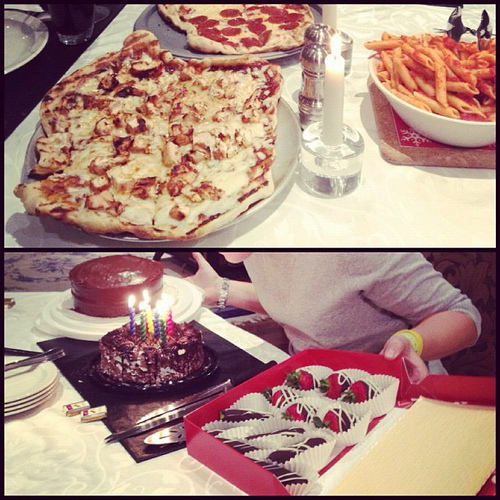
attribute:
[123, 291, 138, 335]
candle — lit, birthday candle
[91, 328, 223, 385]
cake — brown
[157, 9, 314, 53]
pepperoni pizza — cooked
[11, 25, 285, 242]
pizza — freshly cooked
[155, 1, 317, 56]
pizza — freshly cooked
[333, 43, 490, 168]
bowl — white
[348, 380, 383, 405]
strawberries — chocolate covered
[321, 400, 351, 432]
strawberries — chocolate covered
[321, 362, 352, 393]
strawberries — chocolate covered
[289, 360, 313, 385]
strawberries — chocolate covered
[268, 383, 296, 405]
strawberries — chocolate covered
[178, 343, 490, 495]
container — red, plastic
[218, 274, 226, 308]
accessory — worn, wrist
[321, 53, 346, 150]
candle — white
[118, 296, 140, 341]
candle — purple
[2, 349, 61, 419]
plates — white, dinner plates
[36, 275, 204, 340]
platter — white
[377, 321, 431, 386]
hand — left hand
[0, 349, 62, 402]
plate — white, stack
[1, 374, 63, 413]
plate — stack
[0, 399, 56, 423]
plate — stack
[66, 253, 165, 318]
cake — chocolate covered, chocolate, round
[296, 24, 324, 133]
salt shakers — silver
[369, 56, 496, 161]
dish — white, oblong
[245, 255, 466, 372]
shirt — gray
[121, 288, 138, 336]
candle — lit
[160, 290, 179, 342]
candle — lit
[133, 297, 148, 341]
candle — lit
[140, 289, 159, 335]
candle — lit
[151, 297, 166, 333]
candle — lit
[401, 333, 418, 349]
bracelet — yellow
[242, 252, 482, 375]
shirt — gray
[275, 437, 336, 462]
paper — white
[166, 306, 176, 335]
candle — pink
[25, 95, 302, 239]
plate — white